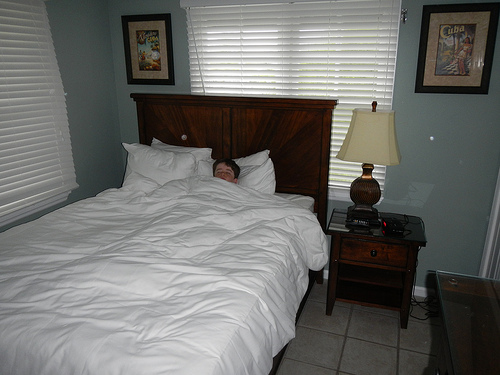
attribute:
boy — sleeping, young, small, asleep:
[210, 159, 243, 184]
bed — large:
[4, 92, 340, 374]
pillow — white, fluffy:
[198, 147, 277, 197]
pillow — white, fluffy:
[119, 141, 195, 188]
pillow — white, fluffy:
[151, 135, 212, 177]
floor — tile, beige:
[276, 281, 431, 375]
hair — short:
[212, 158, 244, 177]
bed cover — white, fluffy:
[0, 172, 330, 374]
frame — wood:
[268, 268, 322, 375]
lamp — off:
[337, 99, 405, 204]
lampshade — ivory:
[335, 109, 407, 168]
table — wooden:
[324, 206, 428, 329]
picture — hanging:
[119, 13, 179, 87]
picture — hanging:
[416, 0, 498, 95]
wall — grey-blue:
[108, 0, 499, 285]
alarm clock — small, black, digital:
[380, 217, 406, 236]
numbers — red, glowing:
[380, 219, 391, 228]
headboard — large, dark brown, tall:
[128, 91, 337, 198]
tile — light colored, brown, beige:
[277, 281, 431, 375]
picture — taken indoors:
[0, 0, 498, 374]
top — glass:
[327, 206, 428, 247]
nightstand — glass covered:
[327, 206, 429, 328]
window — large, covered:
[186, 6, 403, 191]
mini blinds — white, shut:
[178, 2, 403, 197]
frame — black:
[119, 15, 176, 86]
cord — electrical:
[402, 215, 432, 322]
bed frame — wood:
[269, 265, 317, 374]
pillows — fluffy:
[120, 135, 278, 196]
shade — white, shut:
[181, 2, 404, 204]